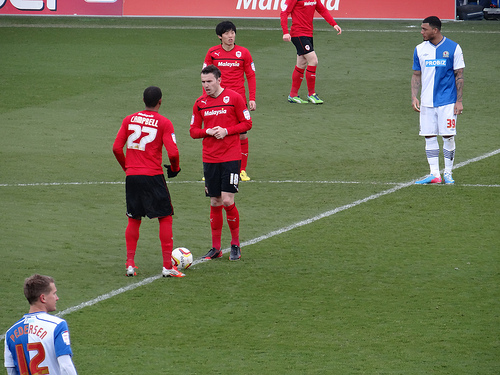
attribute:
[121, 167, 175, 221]
shorts — black